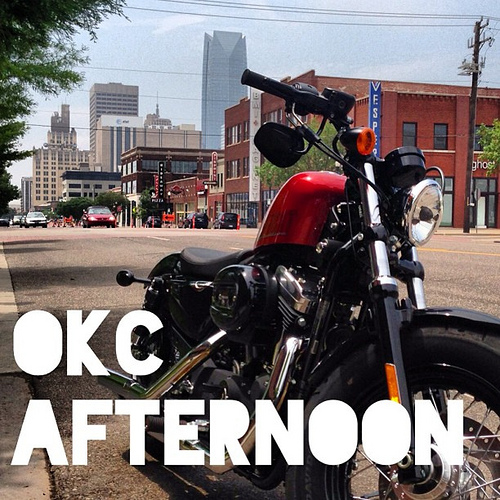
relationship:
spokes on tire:
[345, 391, 484, 492] [292, 319, 497, 482]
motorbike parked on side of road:
[96, 70, 500, 499] [0, 217, 498, 498]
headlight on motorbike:
[400, 178, 442, 245] [96, 70, 500, 499]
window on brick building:
[425, 109, 450, 149] [221, 90, 264, 200]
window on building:
[474, 126, 484, 148] [224, 71, 497, 231]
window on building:
[171, 160, 196, 175] [119, 146, 221, 225]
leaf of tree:
[478, 125, 488, 133] [469, 116, 498, 234]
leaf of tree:
[478, 139, 488, 149] [469, 116, 498, 234]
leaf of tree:
[491, 130, 499, 139] [469, 116, 498, 234]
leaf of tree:
[478, 153, 485, 160] [469, 116, 498, 234]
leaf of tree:
[491, 156, 498, 165] [469, 116, 498, 234]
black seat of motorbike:
[178, 246, 256, 281] [88, 64, 494, 495]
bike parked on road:
[109, 51, 496, 498] [0, 217, 498, 498]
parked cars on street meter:
[144, 213, 238, 230] [170, 213, 252, 227]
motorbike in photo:
[63, 137, 469, 402] [9, 11, 484, 483]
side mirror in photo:
[252, 122, 309, 167] [9, 11, 484, 483]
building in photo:
[200, 27, 252, 162] [9, 11, 484, 483]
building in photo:
[224, 71, 497, 231] [9, 11, 484, 483]